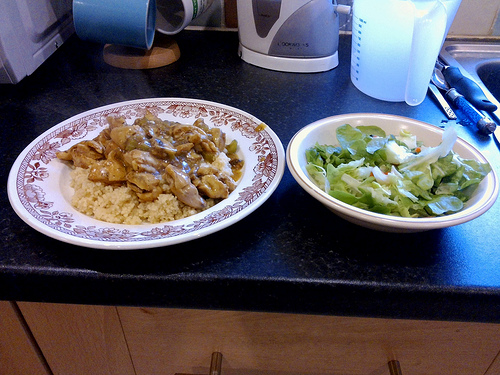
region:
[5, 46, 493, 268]
Plates with a meal of meat and rice and a salad on a kitchen counter.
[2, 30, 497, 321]
Black kitchen counter surface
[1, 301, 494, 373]
Wood-look kitchen cabinets under counter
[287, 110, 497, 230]
Green salad in a round plate with a colored rim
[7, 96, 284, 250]
Meat stew and rice on a china plate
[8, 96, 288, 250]
Round white plate has a decorative transfer-print pattern on edges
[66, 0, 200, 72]
Coffee mugs hanging on a stand on the counter.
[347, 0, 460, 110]
Plastic measuring cup sitting on kitchen counter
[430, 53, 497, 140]
Kitchen utensils sitting on edge of sink on kitchen counter.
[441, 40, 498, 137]
Stainless steel kitchen sink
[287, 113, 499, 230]
Salad in the white bowl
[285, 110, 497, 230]
A white bowl on the counter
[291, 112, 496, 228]
The white bowl is circular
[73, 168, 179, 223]
Rice on the plate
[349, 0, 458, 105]
A measuring jug on the counter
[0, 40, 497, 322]
A counter below the dishes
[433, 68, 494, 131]
A spoon on the counter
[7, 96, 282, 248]
A white plate on the counter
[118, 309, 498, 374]
A drawer beneath the counter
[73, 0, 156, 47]
A blue cup on the counter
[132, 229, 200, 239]
pattern around the plate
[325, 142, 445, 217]
salad in the bowl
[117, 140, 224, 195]
chicken on the plate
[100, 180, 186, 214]
rice on the plate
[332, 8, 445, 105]
water in the container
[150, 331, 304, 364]
wood on the cabinet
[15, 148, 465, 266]
food on the plates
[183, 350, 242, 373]
doorknob on the cabinet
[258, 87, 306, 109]
the countertop is granite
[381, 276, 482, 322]
edge of the counter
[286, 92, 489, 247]
bowl of salad on the counter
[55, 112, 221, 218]
bowl of chinese food on the counter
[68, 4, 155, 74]
blue coffee mug on a rack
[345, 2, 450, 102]
measuring cup on the counter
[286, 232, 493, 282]
black counter top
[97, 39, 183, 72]
base of the coffee mug stand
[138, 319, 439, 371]
wooden drawer under the counter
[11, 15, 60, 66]
side of the microwave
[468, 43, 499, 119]
edge of the sink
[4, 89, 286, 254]
Dinner.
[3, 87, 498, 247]
A balanced meal.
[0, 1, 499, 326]
Dinner on a black countertop.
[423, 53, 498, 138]
Silverware beside a sink.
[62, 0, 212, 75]
Mugs on a kitchen countertop.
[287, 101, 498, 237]
A green salad in a white bowl.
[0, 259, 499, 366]
A black countertop with wood drawer.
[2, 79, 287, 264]
A red and white plate holds a tasty meal.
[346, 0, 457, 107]
This is a measuring cup.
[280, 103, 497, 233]
bowl of lettuce on counter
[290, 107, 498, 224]
a bowl of food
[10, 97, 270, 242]
a plate of food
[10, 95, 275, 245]
a red and white plate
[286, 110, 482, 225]
a white bowl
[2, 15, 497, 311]
the black counter top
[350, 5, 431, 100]
a pitcher on the counter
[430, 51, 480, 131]
utensils on the counter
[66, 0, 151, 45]
a blue mug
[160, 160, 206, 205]
chicken on the plate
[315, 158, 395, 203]
lettuce in the bowl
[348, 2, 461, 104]
clear plastic measuring container